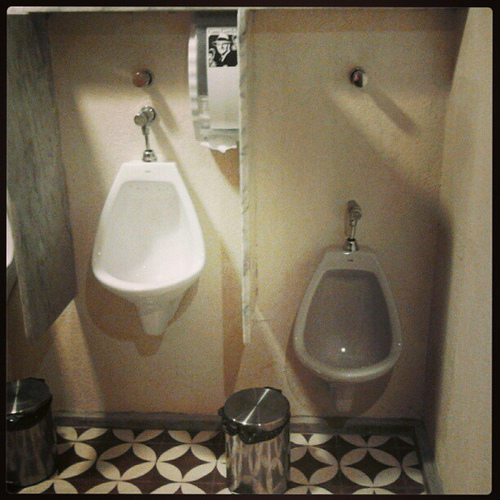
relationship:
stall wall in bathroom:
[224, 11, 267, 360] [21, 20, 452, 480]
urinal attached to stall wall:
[286, 234, 420, 460] [235, 0, 257, 345]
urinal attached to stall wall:
[80, 145, 205, 343] [235, 0, 257, 345]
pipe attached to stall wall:
[336, 199, 368, 249] [235, 0, 257, 345]